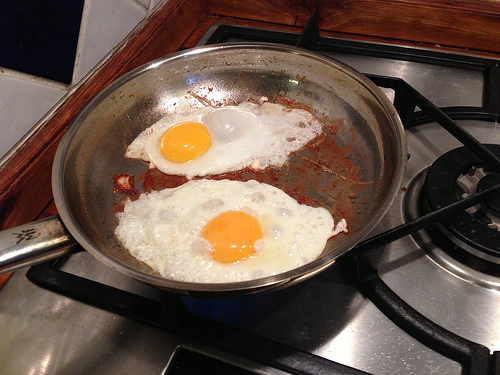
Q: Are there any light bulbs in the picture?
A: No, there are no light bulbs.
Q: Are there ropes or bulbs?
A: No, there are no bulbs or ropes.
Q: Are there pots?
A: No, there are no pots.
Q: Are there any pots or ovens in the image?
A: No, there are no pots or ovens.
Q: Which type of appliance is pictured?
A: The appliance is a gas stove.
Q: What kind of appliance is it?
A: The appliance is a gas stove.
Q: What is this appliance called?
A: This is a gas stove.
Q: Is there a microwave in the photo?
A: No, there are no microwaves.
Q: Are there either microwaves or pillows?
A: No, there are no microwaves or pillows.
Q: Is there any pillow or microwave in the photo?
A: No, there are no microwaves or pillows.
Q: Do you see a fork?
A: No, there are no forks.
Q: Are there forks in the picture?
A: No, there are no forks.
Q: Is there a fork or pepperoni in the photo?
A: No, there are no forks or pepperoni.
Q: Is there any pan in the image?
A: Yes, there is a pan.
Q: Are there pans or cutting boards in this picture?
A: Yes, there is a pan.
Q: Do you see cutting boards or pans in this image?
A: Yes, there is a pan.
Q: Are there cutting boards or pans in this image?
A: Yes, there is a pan.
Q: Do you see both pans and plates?
A: No, there is a pan but no plates.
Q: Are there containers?
A: No, there are no containers.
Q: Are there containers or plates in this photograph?
A: No, there are no containers or plates.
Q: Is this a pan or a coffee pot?
A: This is a pan.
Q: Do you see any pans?
A: Yes, there is a pan.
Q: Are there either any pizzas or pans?
A: Yes, there is a pan.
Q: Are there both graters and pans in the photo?
A: No, there is a pan but no graters.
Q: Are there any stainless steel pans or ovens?
A: Yes, there is a stainless steel pan.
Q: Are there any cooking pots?
A: No, there are no cooking pots.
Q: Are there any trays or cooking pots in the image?
A: No, there are no cooking pots or trays.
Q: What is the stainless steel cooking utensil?
A: The cooking utensil is a pan.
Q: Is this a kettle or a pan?
A: This is a pan.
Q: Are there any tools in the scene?
A: No, there are no tools.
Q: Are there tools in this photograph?
A: No, there are no tools.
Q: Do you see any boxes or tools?
A: No, there are no tools or boxes.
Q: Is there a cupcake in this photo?
A: No, there are no cupcakes.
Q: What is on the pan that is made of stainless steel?
A: The eggs are on the pan.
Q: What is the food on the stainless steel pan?
A: The food is eggs.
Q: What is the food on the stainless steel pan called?
A: The food is eggs.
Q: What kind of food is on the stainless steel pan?
A: The food is eggs.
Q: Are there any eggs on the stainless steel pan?
A: Yes, there are eggs on the pan.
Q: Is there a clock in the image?
A: No, there are no clocks.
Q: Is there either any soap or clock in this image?
A: No, there are no clocks or soaps.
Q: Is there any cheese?
A: No, there is no cheese.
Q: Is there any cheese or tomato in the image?
A: No, there are no cheese or tomatoes.